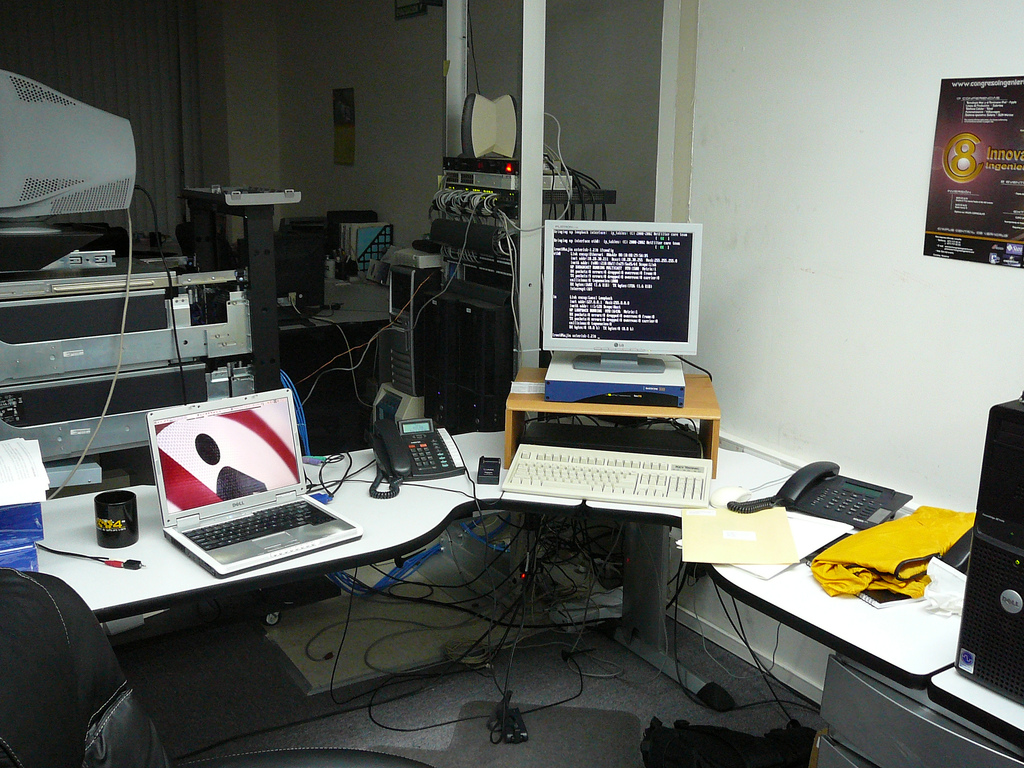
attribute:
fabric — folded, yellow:
[826, 485, 971, 630]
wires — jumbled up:
[358, 496, 698, 764]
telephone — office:
[743, 449, 951, 555]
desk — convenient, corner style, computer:
[8, 362, 1022, 764]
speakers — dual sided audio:
[444, 73, 561, 184]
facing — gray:
[464, 92, 484, 170]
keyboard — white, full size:
[494, 440, 745, 521]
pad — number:
[656, 470, 723, 523]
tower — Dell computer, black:
[946, 380, 1022, 703]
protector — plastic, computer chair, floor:
[444, 689, 633, 763]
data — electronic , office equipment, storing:
[19, 157, 1022, 741]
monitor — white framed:
[537, 213, 708, 361]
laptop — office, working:
[138, 377, 355, 585]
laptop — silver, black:
[134, 367, 376, 596]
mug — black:
[77, 488, 145, 549]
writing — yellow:
[90, 516, 132, 549]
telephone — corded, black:
[362, 403, 479, 516]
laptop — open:
[127, 371, 369, 586]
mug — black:
[83, 469, 168, 563]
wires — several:
[413, 499, 684, 674]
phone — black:
[754, 415, 979, 612]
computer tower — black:
[949, 414, 1021, 656]